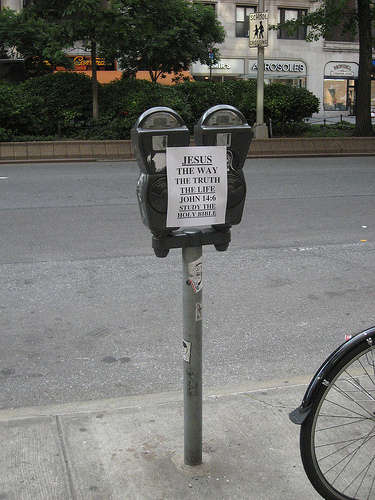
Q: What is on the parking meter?
A: A sign.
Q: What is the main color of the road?
A: Gray.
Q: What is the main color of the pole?
A: Gray.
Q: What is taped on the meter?
A: Flyer.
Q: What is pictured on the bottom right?
A: Bike tire.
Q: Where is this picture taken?
A: On the sidewalk.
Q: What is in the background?
A: Buildings.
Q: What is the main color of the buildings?
A: Gray.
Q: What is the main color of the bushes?
A: Green.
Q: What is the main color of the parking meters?
A: Black.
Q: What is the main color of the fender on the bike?
A: Black.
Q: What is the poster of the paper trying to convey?
A: Message.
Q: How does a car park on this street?
A: Meter payment.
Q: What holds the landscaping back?
A: Wall.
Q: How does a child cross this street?
A: Crosswalk.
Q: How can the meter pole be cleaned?
A: Scrape stickers off.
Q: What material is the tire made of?
A: Rubber.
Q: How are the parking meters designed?
A: Doubles.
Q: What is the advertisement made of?
A: Paper.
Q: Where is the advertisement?
A: On the parking meter.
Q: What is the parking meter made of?
A: Metal.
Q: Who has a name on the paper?
A: Jesus.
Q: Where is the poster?
A: On the meter.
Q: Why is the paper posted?
A: To study the bible.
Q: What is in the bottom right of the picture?
A: A bike tire.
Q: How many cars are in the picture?
A: None.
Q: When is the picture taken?
A: During the day.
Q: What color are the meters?
A: Black.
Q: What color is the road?
A: Gray.